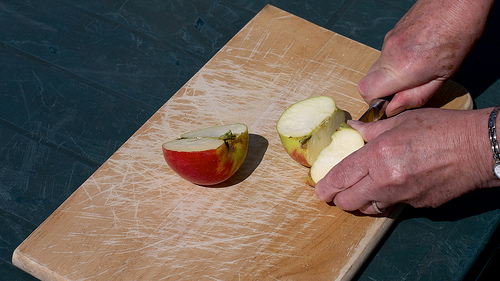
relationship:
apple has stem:
[181, 106, 244, 173] [222, 132, 238, 158]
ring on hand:
[366, 202, 410, 231] [358, 117, 425, 208]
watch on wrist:
[486, 112, 499, 160] [471, 110, 497, 169]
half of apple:
[271, 100, 355, 182] [181, 106, 244, 173]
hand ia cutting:
[358, 117, 425, 208] [315, 80, 406, 180]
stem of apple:
[222, 132, 238, 158] [181, 106, 244, 173]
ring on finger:
[366, 202, 410, 231] [348, 188, 406, 235]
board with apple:
[231, 31, 298, 136] [181, 106, 244, 173]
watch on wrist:
[485, 105, 498, 179] [471, 110, 497, 169]